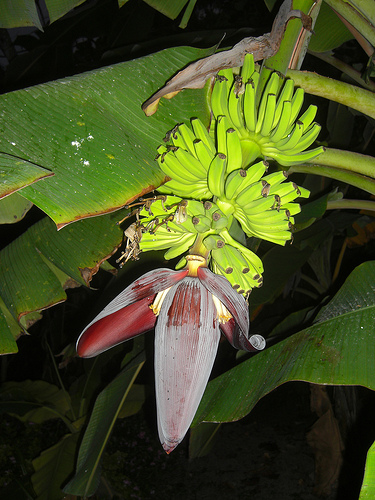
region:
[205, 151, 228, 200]
a green banana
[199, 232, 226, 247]
a green banana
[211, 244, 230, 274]
a green banana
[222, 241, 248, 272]
a green banana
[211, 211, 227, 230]
a green banana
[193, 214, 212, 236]
a green banana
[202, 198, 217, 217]
a green banana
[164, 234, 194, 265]
a green banana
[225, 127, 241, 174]
a green banana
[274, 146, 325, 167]
a green banana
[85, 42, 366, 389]
a banana tree has grown from the ground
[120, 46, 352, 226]
the bananas are yellow and green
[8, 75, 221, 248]
the leaves have white spots on them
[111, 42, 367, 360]
the bananas are attached to the tree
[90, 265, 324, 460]
the flower is red and white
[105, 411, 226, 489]
the ground has rocks and dirt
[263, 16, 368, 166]
the stems are green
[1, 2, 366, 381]
forest landscape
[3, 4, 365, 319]
the leaves are green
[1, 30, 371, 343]
leaves are covering the landscape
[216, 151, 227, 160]
the brown end of the banana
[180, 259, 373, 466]
a large green leaf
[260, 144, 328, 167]
a green banana on the tree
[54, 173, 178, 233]
a brown edge of the leaf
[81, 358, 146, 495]
a vein on the leaf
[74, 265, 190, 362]
a brown leaf on the tree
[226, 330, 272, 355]
a curled up brown leaf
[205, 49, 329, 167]
a bunch of bananas on the tree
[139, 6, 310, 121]
a shriveled leaf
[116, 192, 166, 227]
twigs on the leaf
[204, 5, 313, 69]
the bird is gray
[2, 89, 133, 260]
the leaves are green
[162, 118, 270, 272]
the bananas are yellow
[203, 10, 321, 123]
bird is on bananas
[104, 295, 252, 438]
the flower is purple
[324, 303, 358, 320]
white dots on leaves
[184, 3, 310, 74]
this is a bird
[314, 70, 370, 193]
these are the stems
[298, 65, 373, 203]
the stems are green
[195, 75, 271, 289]
the bananas are in a bushel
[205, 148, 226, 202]
A green banana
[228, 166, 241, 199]
A green banana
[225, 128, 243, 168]
A green banana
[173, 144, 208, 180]
A green banana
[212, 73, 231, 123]
A green banana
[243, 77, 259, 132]
A green banana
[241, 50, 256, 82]
A green banana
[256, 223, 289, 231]
A green banana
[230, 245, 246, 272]
A green banana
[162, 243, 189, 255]
A green banana